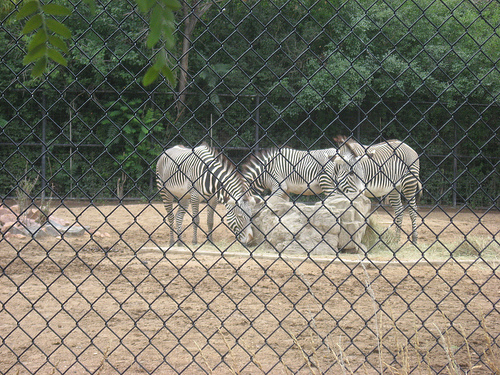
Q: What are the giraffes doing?
A: Eating.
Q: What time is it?
A: Noon.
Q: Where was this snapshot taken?
A: The zoo.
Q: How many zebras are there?
A: 3.